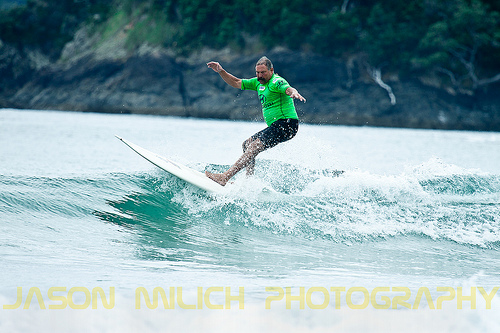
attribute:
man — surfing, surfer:
[210, 54, 292, 182]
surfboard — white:
[124, 138, 228, 206]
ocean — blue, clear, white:
[6, 123, 499, 315]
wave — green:
[15, 171, 494, 224]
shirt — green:
[239, 74, 299, 120]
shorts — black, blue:
[250, 118, 301, 146]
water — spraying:
[222, 120, 328, 199]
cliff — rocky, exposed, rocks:
[17, 37, 498, 125]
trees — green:
[8, 2, 495, 63]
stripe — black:
[276, 94, 288, 120]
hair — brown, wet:
[257, 59, 274, 68]